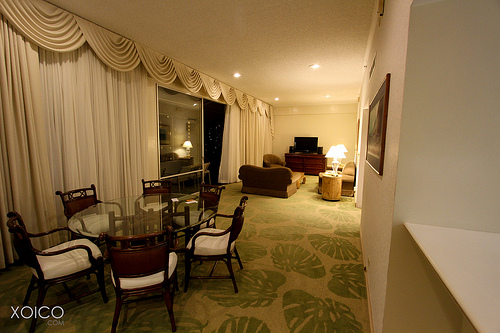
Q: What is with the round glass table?
A: The chairs.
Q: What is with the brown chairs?
A: White cushions.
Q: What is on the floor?
A: Large leaf pattern.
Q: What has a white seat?
A: The wooden chair.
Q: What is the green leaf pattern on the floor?
A: Large.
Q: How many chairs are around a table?
A: Six.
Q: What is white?
A: Curtains.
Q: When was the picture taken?
A: Nighttime.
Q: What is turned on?
A: Lights.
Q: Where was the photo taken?
A: In a house.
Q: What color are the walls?
A: White.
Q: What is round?
A: Table.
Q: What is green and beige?
A: Carpet.